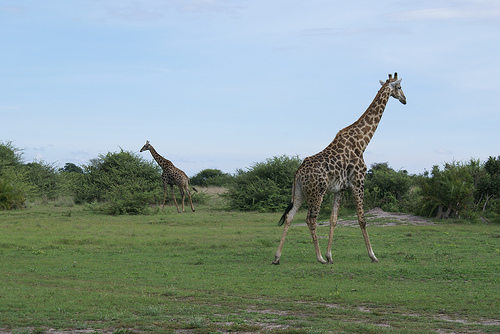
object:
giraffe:
[272, 71, 405, 263]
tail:
[278, 181, 296, 226]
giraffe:
[140, 139, 198, 213]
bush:
[86, 151, 156, 210]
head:
[377, 72, 407, 106]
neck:
[342, 95, 387, 148]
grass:
[68, 212, 255, 276]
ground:
[13, 212, 494, 328]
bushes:
[232, 158, 498, 214]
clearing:
[190, 169, 232, 187]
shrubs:
[0, 141, 40, 207]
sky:
[11, 0, 498, 155]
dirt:
[368, 206, 416, 226]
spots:
[328, 141, 356, 186]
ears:
[394, 72, 398, 78]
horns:
[394, 71, 398, 78]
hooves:
[272, 261, 279, 265]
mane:
[349, 101, 373, 126]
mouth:
[400, 97, 407, 105]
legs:
[351, 187, 379, 263]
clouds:
[193, 5, 491, 65]